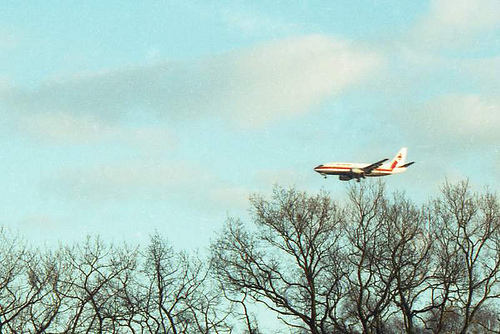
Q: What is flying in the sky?
A: Plane.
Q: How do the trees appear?
A: Bare and dead.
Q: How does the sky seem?
A: Cloudy.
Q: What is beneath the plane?
A: Trees.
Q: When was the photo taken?
A: In the daytime.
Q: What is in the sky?
A: Clouds.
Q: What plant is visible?
A: Trees.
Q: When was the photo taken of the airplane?
A: Daytime.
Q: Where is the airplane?
A: In the air.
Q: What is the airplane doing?
A: Landing.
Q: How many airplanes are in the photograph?
A: One.